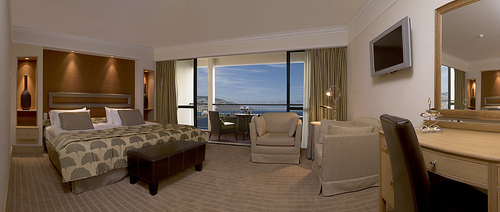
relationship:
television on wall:
[362, 15, 415, 80] [351, 4, 434, 126]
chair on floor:
[250, 111, 306, 168] [10, 131, 381, 211]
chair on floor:
[382, 116, 440, 211] [10, 131, 381, 211]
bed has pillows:
[42, 102, 209, 190] [49, 107, 145, 127]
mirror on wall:
[434, 2, 499, 119] [351, 4, 434, 126]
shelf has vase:
[18, 110, 38, 126] [21, 73, 33, 110]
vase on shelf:
[21, 73, 33, 110] [18, 110, 38, 126]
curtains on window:
[155, 61, 177, 123] [176, 52, 314, 144]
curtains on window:
[308, 50, 348, 119] [176, 52, 314, 144]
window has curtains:
[176, 52, 314, 144] [155, 61, 177, 123]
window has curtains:
[176, 52, 314, 144] [308, 50, 348, 119]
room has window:
[5, 0, 499, 211] [176, 52, 314, 144]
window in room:
[176, 52, 314, 144] [5, 0, 499, 211]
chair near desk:
[382, 116, 440, 211] [379, 115, 499, 211]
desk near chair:
[379, 115, 499, 211] [382, 116, 440, 211]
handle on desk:
[429, 158, 438, 167] [379, 115, 499, 211]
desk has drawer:
[379, 115, 499, 211] [420, 149, 490, 194]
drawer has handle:
[420, 149, 490, 194] [429, 158, 438, 167]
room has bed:
[5, 0, 499, 211] [42, 102, 209, 190]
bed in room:
[42, 102, 209, 190] [5, 0, 499, 211]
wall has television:
[351, 4, 434, 126] [362, 15, 415, 80]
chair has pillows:
[250, 111, 306, 168] [256, 114, 298, 136]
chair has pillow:
[250, 111, 306, 168] [255, 116, 268, 135]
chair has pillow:
[250, 111, 306, 168] [291, 115, 299, 140]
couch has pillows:
[311, 119, 381, 196] [318, 121, 376, 149]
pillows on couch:
[318, 121, 376, 149] [311, 119, 381, 196]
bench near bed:
[129, 140, 205, 195] [42, 102, 209, 190]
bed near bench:
[42, 102, 209, 190] [129, 140, 205, 195]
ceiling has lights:
[4, 2, 435, 61] [66, 50, 116, 61]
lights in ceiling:
[66, 50, 116, 61] [4, 2, 435, 61]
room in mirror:
[5, 0, 499, 211] [434, 2, 499, 119]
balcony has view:
[198, 99, 304, 145] [201, 68, 303, 110]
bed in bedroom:
[42, 102, 209, 190] [5, 0, 499, 211]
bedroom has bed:
[5, 0, 499, 211] [42, 102, 209, 190]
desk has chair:
[379, 115, 499, 211] [382, 116, 440, 211]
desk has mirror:
[379, 115, 499, 211] [434, 2, 499, 119]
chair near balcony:
[250, 111, 306, 168] [198, 99, 304, 145]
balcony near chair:
[198, 99, 304, 145] [250, 111, 306, 168]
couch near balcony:
[311, 119, 381, 196] [198, 99, 304, 145]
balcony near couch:
[198, 99, 304, 145] [311, 119, 381, 196]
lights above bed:
[66, 50, 116, 61] [42, 102, 209, 190]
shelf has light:
[18, 110, 38, 126] [18, 56, 31, 64]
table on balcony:
[236, 111, 255, 135] [198, 99, 304, 145]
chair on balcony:
[209, 112, 234, 143] [198, 99, 304, 145]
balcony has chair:
[198, 99, 304, 145] [209, 112, 234, 143]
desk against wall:
[379, 115, 499, 211] [351, 4, 434, 126]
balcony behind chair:
[198, 99, 304, 145] [250, 111, 306, 168]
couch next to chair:
[311, 119, 381, 196] [250, 111, 306, 168]